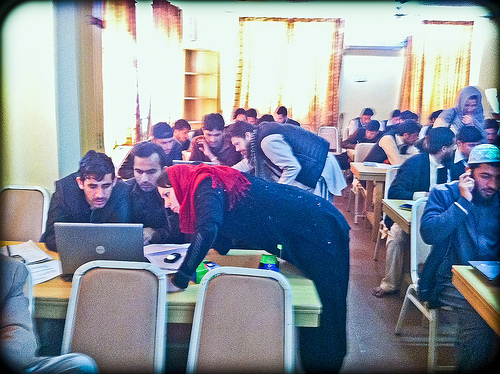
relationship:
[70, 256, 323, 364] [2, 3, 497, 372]
chairs in classroom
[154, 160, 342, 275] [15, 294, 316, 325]
woman on table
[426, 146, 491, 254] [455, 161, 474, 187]
man with cell phone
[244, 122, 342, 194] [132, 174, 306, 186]
man on table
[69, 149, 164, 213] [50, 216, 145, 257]
men looking at laptop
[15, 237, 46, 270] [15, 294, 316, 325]
paperwork on table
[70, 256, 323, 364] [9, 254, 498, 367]
chairs on front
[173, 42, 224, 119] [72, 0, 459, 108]
bookcase in back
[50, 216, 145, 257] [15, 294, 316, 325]
laptop on table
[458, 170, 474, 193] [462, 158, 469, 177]
finger in ear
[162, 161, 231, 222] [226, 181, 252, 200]
scarf with fringe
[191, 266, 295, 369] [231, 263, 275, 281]
chair with metal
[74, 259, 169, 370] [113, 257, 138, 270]
chair with metal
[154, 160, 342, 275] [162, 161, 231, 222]
woman in scarf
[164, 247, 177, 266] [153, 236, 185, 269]
cell phone on papers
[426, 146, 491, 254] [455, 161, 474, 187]
man holding cell phone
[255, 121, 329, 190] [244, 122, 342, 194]
vest on man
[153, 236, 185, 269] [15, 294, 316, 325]
papers on table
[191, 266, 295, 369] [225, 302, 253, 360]
chair with brown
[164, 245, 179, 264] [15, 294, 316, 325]
mouse on table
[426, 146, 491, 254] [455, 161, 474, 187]
man talking on cell phone